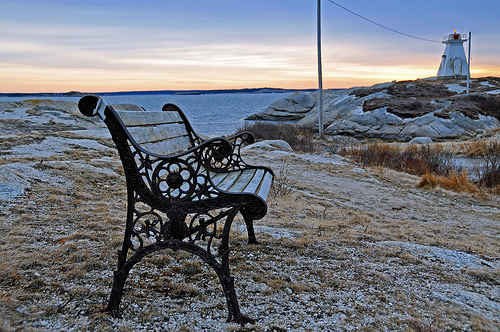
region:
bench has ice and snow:
[91, 92, 263, 202]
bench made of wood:
[119, 92, 319, 220]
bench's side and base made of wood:
[74, 88, 274, 326]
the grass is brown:
[31, 99, 486, 301]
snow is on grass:
[6, 90, 474, 314]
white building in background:
[422, 25, 482, 95]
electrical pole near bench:
[311, 0, 349, 137]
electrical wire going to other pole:
[316, 0, 491, 68]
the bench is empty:
[69, 80, 329, 318]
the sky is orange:
[13, 55, 495, 117]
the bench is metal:
[26, 82, 256, 315]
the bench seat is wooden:
[73, 90, 293, 291]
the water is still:
[201, 96, 246, 121]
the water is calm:
[195, 94, 247, 119]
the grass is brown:
[401, 143, 476, 203]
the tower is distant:
[421, 10, 488, 88]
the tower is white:
[416, 17, 493, 84]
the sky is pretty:
[19, 44, 289, 91]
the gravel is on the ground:
[319, 215, 470, 315]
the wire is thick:
[376, 14, 426, 49]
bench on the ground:
[69, 83, 281, 279]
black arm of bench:
[165, 136, 226, 195]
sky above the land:
[199, 18, 274, 78]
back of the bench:
[130, 91, 220, 161]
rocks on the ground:
[294, 245, 371, 312]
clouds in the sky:
[166, 24, 257, 79]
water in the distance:
[203, 91, 244, 127]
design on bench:
[143, 148, 210, 218]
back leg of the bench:
[65, 265, 145, 325]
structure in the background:
[419, 18, 481, 88]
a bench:
[94, 98, 384, 296]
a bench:
[28, 8, 309, 289]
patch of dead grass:
[383, 138, 493, 213]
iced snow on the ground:
[301, 185, 438, 305]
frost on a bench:
[50, 75, 282, 330]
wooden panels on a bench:
[138, 108, 255, 193]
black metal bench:
[82, 100, 252, 325]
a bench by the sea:
[72, 70, 296, 327]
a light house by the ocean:
[422, 14, 477, 99]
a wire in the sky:
[360, 11, 445, 63]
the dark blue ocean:
[191, 91, 270, 130]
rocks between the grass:
[18, 136, 74, 213]